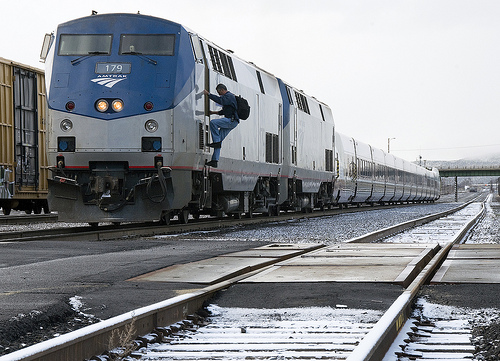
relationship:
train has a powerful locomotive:
[36, 11, 441, 221] [42, 10, 337, 223]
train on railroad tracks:
[36, 11, 441, 221] [68, 201, 418, 357]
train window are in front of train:
[58, 34, 113, 57] [36, 11, 441, 221]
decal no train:
[91, 51, 137, 96] [36, 11, 441, 221]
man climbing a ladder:
[203, 83, 238, 168] [198, 62, 218, 236]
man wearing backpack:
[195, 73, 249, 176] [224, 90, 252, 123]